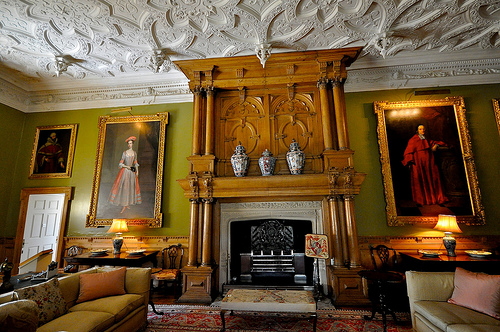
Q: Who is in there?
A: No one.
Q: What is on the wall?
A: Victorian pictures.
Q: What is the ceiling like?
A: 3D pattern.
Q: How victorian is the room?
A: Very Victorian.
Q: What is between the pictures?
A: Fireplace.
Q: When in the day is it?
A: Afternoon.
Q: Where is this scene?
A: Living room.